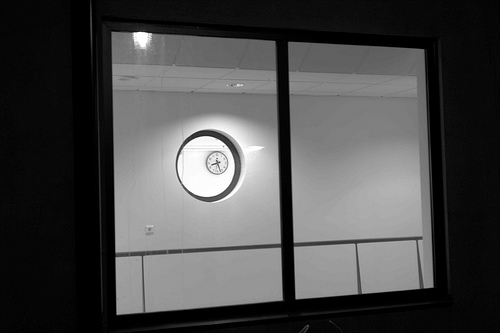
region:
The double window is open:
[79, 10, 461, 331]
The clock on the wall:
[203, 147, 230, 179]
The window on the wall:
[161, 117, 257, 209]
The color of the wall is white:
[308, 107, 410, 225]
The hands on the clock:
[207, 157, 227, 174]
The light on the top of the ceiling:
[123, 30, 163, 55]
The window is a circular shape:
[172, 126, 248, 205]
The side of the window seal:
[59, 10, 123, 327]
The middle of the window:
[266, 35, 306, 307]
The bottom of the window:
[96, 282, 466, 329]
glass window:
[104, 21, 445, 327]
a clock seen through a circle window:
[206, 154, 232, 175]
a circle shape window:
[169, 121, 251, 203]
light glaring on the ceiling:
[132, 34, 155, 51]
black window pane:
[271, 30, 298, 305]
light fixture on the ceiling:
[225, 76, 249, 88]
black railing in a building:
[112, 227, 434, 314]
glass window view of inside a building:
[101, 27, 450, 318]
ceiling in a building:
[113, 23, 423, 103]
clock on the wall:
[204, 150, 231, 179]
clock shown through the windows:
[189, 138, 237, 183]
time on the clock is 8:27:
[202, 149, 230, 179]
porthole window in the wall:
[159, 108, 254, 208]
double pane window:
[80, 9, 464, 299]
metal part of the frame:
[274, 35, 299, 322]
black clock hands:
[209, 156, 225, 173]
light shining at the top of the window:
[133, 30, 153, 47]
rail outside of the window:
[129, 239, 381, 259]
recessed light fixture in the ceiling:
[229, 79, 246, 93]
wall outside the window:
[296, 112, 356, 210]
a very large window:
[106, 25, 442, 319]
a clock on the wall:
[201, 147, 231, 178]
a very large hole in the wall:
[166, 104, 257, 223]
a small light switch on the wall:
[141, 224, 157, 236]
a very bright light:
[121, 23, 163, 63]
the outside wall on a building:
[18, 20, 56, 324]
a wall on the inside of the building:
[295, 112, 401, 201]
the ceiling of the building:
[164, 58, 266, 95]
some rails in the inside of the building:
[102, 233, 427, 308]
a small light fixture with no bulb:
[223, 78, 245, 98]